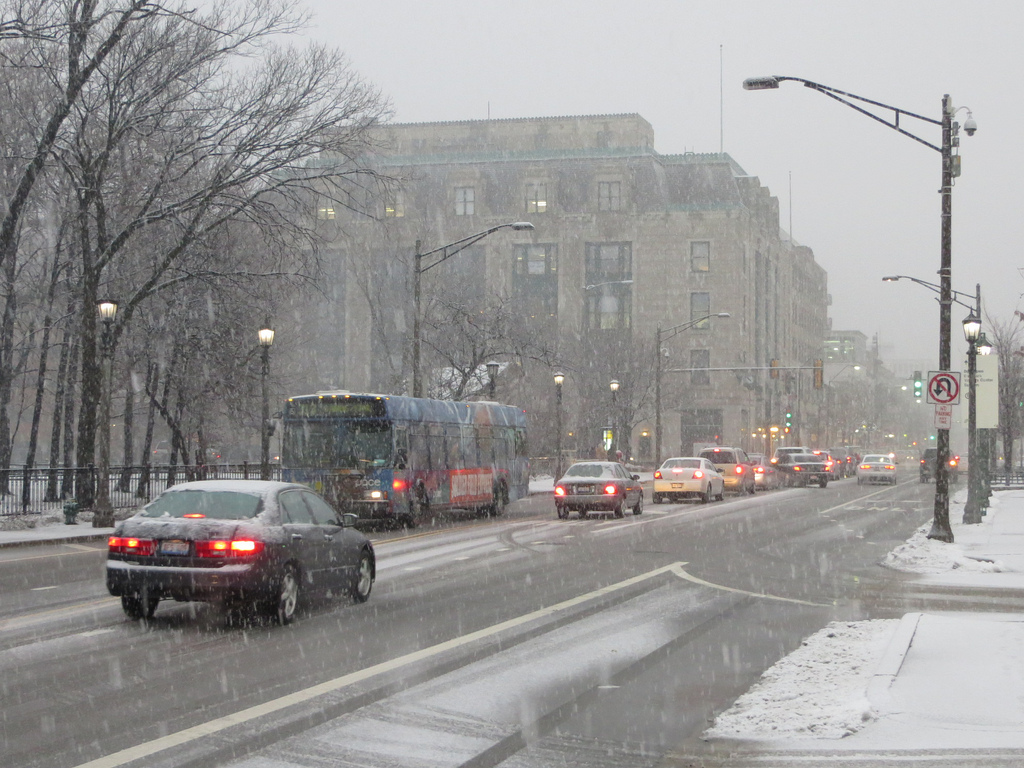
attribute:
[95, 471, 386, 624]
traffic — covered, stopped, snow covered, compact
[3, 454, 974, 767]
street — snow, snowy, snow-covered, marked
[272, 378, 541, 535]
bus — city, blue, public, driving, city bus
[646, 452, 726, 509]
traffic — white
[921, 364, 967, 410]
sign — white, red, black, no u-turn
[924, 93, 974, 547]
post — lamp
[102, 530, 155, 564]
lights — red, rear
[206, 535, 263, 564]
lights — red, rear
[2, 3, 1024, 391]
sky — gray, cloudy, overcast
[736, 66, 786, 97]
lamps — lined, on, street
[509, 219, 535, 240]
lamps — lined, on, street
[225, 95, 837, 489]
building — large, brown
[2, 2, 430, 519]
tree — leafless, barren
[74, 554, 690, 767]
line — white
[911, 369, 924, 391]
light — green, traffic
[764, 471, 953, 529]
lane — turn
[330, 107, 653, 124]
roof — snow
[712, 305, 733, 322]
light — off